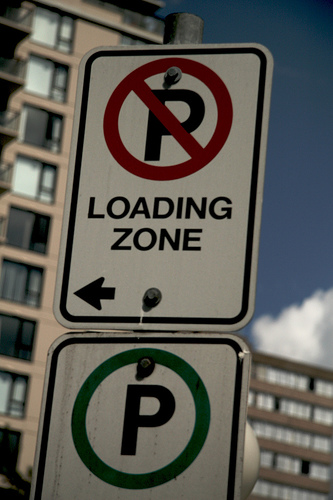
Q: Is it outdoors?
A: Yes, it is outdoors.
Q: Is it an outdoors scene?
A: Yes, it is outdoors.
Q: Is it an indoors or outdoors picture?
A: It is outdoors.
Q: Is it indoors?
A: No, it is outdoors.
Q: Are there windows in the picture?
A: Yes, there is a window.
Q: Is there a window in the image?
A: Yes, there is a window.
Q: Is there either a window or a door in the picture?
A: Yes, there is a window.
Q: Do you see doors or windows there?
A: Yes, there is a window.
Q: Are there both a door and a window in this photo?
A: No, there is a window but no doors.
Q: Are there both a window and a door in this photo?
A: No, there is a window but no doors.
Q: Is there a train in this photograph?
A: No, there are no trains.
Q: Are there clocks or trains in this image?
A: No, there are no trains or clocks.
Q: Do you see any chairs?
A: No, there are no chairs.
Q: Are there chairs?
A: No, there are no chairs.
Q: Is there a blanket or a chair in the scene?
A: No, there are no chairs or blankets.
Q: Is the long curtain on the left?
A: Yes, the curtain is on the left of the image.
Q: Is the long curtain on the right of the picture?
A: No, the curtain is on the left of the image.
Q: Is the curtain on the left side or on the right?
A: The curtain is on the left of the image.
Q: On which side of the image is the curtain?
A: The curtain is on the left of the image.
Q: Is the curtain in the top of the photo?
A: Yes, the curtain is in the top of the image.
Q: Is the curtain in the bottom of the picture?
A: No, the curtain is in the top of the image.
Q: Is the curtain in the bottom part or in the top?
A: The curtain is in the top of the image.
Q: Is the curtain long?
A: Yes, the curtain is long.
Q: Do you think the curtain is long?
A: Yes, the curtain is long.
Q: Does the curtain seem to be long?
A: Yes, the curtain is long.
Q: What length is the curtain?
A: The curtain is long.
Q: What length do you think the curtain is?
A: The curtain is long.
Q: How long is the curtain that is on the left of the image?
A: The curtain is long.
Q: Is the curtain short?
A: No, the curtain is long.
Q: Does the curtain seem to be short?
A: No, the curtain is long.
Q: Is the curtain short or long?
A: The curtain is long.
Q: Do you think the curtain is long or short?
A: The curtain is long.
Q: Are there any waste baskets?
A: No, there are no waste baskets.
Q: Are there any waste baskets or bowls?
A: No, there are no waste baskets or bowls.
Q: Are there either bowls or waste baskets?
A: No, there are no waste baskets or bowls.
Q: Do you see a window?
A: Yes, there are windows.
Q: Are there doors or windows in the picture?
A: Yes, there are windows.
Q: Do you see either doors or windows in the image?
A: Yes, there are windows.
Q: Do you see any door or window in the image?
A: Yes, there are windows.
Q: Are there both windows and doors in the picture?
A: No, there are windows but no doors.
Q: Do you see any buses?
A: No, there are no buses.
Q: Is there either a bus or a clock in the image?
A: No, there are no buses or clocks.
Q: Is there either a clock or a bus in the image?
A: No, there are no buses or clocks.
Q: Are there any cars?
A: No, there are no cars.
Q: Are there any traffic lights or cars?
A: No, there are no cars or traffic lights.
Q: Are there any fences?
A: No, there are no fences.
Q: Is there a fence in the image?
A: No, there are no fences.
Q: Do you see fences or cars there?
A: No, there are no fences or cars.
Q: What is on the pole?
A: The sign is on the pole.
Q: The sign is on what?
A: The sign is on the pole.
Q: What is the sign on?
A: The sign is on the pole.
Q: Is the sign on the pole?
A: Yes, the sign is on the pole.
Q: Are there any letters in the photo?
A: Yes, there are letters.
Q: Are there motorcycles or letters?
A: Yes, there are letters.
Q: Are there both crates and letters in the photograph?
A: No, there are letters but no crates.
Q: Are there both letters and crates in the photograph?
A: No, there are letters but no crates.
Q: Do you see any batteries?
A: No, there are no batteries.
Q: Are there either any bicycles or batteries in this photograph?
A: No, there are no batteries or bicycles.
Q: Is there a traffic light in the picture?
A: No, there are no traffic lights.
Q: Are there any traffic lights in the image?
A: No, there are no traffic lights.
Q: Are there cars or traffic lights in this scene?
A: No, there are no traffic lights or cars.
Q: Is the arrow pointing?
A: Yes, the arrow is pointing.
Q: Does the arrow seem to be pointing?
A: Yes, the arrow is pointing.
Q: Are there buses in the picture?
A: No, there are no buses.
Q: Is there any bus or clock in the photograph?
A: No, there are no buses or clocks.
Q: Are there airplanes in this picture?
A: No, there are no airplanes.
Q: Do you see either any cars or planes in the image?
A: No, there are no planes or cars.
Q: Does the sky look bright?
A: Yes, the sky is bright.